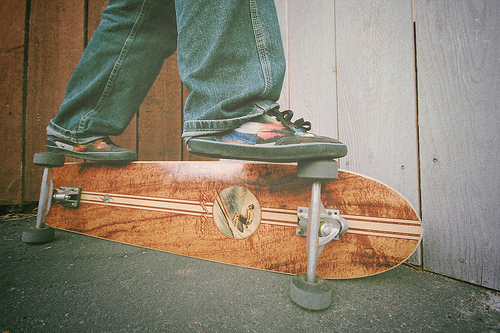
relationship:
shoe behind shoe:
[45, 135, 138, 162] [182, 107, 350, 161]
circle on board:
[211, 184, 262, 241] [20, 150, 423, 311]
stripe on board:
[79, 189, 422, 244] [20, 150, 423, 311]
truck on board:
[32, 165, 82, 230] [20, 150, 423, 311]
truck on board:
[296, 178, 350, 285] [20, 150, 423, 311]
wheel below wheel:
[32, 149, 65, 168] [19, 223, 56, 243]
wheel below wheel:
[293, 157, 340, 180] [286, 275, 335, 311]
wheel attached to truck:
[32, 149, 65, 168] [34, 168, 74, 222]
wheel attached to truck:
[19, 223, 56, 243] [34, 168, 74, 222]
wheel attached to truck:
[293, 157, 340, 180] [297, 180, 336, 281]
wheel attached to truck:
[286, 275, 335, 311] [297, 180, 336, 281]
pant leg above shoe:
[42, 0, 175, 133] [46, 126, 135, 164]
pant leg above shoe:
[182, 0, 282, 137] [185, 103, 348, 163]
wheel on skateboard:
[293, 157, 340, 180] [17, 154, 414, 279]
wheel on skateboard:
[32, 149, 65, 168] [17, 154, 414, 279]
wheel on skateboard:
[19, 223, 56, 243] [17, 154, 414, 279]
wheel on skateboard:
[286, 275, 335, 311] [17, 154, 414, 279]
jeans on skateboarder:
[52, 0, 288, 132] [47, 15, 368, 158]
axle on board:
[278, 194, 363, 262] [20, 150, 423, 311]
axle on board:
[28, 168, 91, 225] [20, 150, 423, 311]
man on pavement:
[42, 0, 347, 163] [0, 247, 498, 331]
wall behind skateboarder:
[276, 1, 498, 290] [75, 6, 296, 154]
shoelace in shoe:
[273, 104, 313, 142] [182, 107, 350, 161]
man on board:
[42, 0, 347, 163] [20, 150, 423, 311]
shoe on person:
[186, 106, 348, 163] [45, 6, 322, 186]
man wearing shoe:
[42, 0, 347, 163] [186, 106, 348, 163]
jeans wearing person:
[52, 0, 288, 132] [77, 14, 292, 151]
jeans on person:
[52, 0, 288, 132] [63, 9, 316, 157]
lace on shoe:
[279, 110, 325, 143] [182, 107, 350, 161]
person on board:
[37, 1, 347, 165] [26, 154, 438, 297]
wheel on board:
[293, 157, 340, 180] [26, 154, 438, 297]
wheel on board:
[290, 273, 333, 311] [26, 154, 438, 297]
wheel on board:
[19, 212, 51, 239] [26, 154, 438, 297]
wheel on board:
[29, 144, 71, 174] [26, 154, 438, 297]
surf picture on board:
[211, 180, 262, 245] [20, 150, 423, 311]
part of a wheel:
[303, 299, 316, 306] [286, 275, 335, 311]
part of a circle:
[224, 211, 230, 221] [212, 185, 261, 241]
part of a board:
[128, 215, 168, 239] [61, 163, 304, 277]